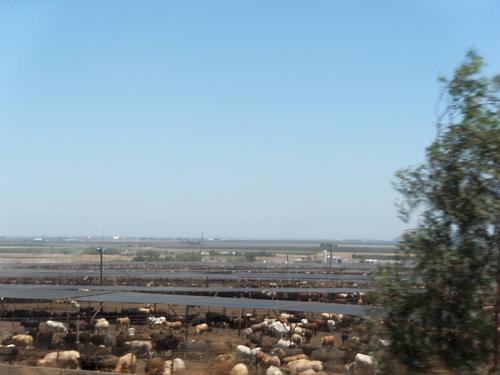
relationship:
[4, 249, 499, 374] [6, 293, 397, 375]
pasture filled with cows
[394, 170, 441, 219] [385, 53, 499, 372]
branch of tree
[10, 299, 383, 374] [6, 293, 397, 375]
fence around cows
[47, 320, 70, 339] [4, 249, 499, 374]
cow in pasture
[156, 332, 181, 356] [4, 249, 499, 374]
cow in pasture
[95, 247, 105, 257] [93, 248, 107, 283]
light on pole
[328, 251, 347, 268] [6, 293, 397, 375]
building behind cows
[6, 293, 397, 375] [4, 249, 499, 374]
cows in pasture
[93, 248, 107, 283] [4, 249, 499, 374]
pole sitting in pasture